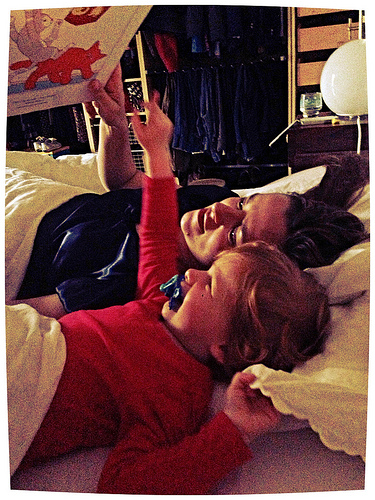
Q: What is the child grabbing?
A: Pillow.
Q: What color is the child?
A: White.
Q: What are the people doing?
A: Reading a book.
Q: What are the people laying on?
A: A bed.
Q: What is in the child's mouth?
A: A pacifier.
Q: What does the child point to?
A: Book.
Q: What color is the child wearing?
A: Red.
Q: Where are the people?
A: In a bedroom.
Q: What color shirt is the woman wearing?
A: Blue.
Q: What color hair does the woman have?
A: Dark.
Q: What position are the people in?
A: Lying down.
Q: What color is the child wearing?
A: Red.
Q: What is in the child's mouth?
A: Pacifier.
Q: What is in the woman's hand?
A: Book.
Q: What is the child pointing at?
A: The book.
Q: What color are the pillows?
A: White.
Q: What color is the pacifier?
A: Blue.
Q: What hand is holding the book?
A: The right hand.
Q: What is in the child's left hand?
A: Pillow.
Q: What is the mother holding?
A: A book.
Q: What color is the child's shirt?
A: Red.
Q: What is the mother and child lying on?
A: Bed.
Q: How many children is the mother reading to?
A: One.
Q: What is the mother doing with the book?
A: Reading it.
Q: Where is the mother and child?
A: In the bedroom.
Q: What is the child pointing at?
A: Storybook.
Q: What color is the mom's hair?
A: Dark Brown.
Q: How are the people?
A: Laying down.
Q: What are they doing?
A: Reading a story.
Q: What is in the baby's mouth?
A: A pacifier.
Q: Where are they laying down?
A: In bed.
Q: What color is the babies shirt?
A: Red.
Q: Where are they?
A: In the bedroom.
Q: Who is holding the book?
A: The woman.